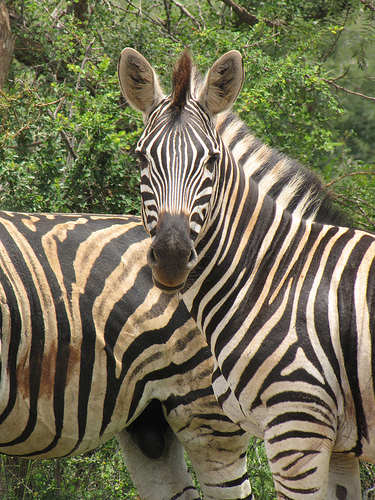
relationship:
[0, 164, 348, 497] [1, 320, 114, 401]
zebra covered in dirt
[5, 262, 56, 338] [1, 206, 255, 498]
spot on a zebra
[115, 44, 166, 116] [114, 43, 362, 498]
ear of zebra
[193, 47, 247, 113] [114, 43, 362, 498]
ear of zebra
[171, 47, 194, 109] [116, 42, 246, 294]
hair on head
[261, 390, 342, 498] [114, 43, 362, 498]
leg of zebra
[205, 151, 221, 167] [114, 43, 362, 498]
eye of zebra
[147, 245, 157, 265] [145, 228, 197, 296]
nostril of muzzle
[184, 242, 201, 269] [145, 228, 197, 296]
nostril of muzzle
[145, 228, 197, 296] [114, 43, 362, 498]
muzzle of zebra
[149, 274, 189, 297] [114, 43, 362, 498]
mouth of zebra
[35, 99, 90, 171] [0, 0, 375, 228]
leaves in vegatation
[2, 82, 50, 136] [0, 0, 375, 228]
leaves in vegatation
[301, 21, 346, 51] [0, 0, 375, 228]
leaves in vegatation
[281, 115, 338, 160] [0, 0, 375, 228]
leaves in vegatation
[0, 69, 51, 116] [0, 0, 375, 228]
leaves in vegatation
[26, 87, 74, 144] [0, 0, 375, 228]
leaves in vegatation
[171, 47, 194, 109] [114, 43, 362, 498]
hair on a zebra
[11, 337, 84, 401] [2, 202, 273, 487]
dirt on a zebra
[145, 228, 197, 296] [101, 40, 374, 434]
muzzle on a zebra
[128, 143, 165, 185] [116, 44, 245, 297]
eye in a head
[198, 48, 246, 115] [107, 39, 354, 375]
ear on a zebra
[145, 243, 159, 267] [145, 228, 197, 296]
nostril on a muzzle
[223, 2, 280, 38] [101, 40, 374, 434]
tree branch behind zebra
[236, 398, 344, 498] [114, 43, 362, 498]
legs of zebra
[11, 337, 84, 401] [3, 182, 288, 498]
dirt on zebra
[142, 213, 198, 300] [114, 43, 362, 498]
muzzle of zebra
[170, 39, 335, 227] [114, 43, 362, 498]
mane of zebra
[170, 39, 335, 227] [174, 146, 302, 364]
mane on neck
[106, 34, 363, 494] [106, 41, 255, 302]
head of zebra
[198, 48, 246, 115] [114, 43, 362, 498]
ear of zebra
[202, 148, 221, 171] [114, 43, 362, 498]
eye of zebra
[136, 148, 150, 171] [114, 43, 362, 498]
eye of zebra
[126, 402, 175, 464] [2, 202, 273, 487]
testicles of zebra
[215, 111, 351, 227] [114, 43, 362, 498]
mane of zebra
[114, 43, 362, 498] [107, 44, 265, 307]
zebra has head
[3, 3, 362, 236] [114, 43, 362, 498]
vegatation behind zebra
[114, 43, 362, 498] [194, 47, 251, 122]
zebra has ear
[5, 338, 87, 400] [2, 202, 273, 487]
spot on zebra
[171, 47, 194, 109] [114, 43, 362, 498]
hair on zebra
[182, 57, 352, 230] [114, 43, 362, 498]
hair on zebra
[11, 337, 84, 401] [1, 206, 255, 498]
dirt on zebra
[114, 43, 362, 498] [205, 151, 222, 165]
zebra has eye